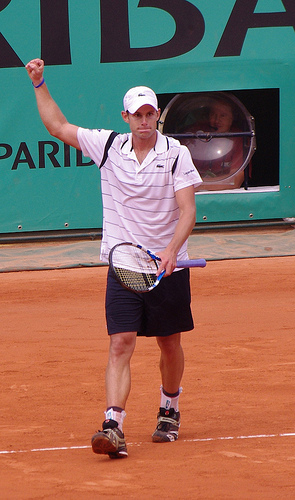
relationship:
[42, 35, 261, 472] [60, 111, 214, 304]
man in white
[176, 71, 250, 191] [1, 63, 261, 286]
person in background